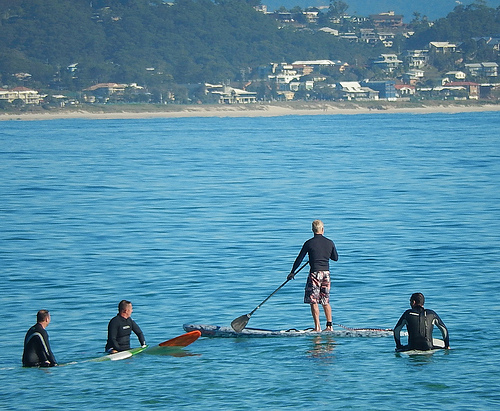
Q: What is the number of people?
A: 4.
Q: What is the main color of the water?
A: Blue.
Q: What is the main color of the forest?
A: Green.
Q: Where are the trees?
A: Background.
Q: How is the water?
A: Blue.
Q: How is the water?
A: Smooth.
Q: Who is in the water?
A: Four men.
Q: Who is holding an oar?
A: A man.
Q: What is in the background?
A: Buildings.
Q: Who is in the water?
A: Four men.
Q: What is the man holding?
A: A paddle.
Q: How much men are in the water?
A: Four.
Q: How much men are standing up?
A: One.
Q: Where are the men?
A: In the ocean.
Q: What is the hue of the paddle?
A: Black.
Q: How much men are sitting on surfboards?
A: Three.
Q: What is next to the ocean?
A: A city.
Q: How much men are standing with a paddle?
A: One.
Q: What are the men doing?
A: Paddle boarding and surfing.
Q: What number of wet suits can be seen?
A: 3.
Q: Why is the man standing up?
A: He is paddle boarding.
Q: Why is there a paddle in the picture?
A: He is paddling boarding, to move.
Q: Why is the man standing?
A: To paddle.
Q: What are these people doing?
A: Surfing.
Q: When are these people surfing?
A: Afternoon.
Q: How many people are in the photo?
A: 4.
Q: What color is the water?
A: Blue.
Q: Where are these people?
A: In water.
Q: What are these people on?
A: Surfboards.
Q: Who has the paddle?
A: Standing man.